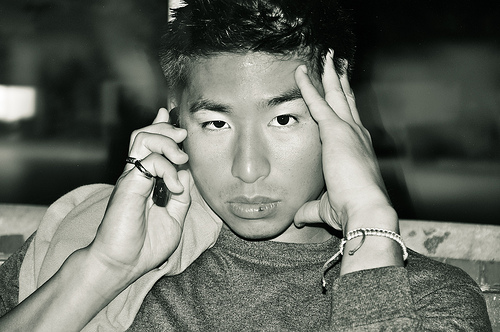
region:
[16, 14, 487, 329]
a boy on a cell phone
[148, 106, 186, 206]
a cell phone in a hand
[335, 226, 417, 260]
a bracelet on a wrist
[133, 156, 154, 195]
a ring on a finger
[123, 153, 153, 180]
a couple of rings on fingers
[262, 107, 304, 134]
th eye of a boy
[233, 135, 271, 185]
the nose of a boy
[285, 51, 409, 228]
a left hand of a boy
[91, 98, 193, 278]
the right hand of a boy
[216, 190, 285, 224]
the lips on a boy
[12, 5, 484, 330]
a man holds a cell phone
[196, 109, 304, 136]
eyes are black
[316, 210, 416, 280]
bracelet on a wrist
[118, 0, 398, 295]
boy has short hair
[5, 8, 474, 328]
man holds a phone on right hand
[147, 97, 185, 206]
cell phone is black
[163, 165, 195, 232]
thumb holding a phone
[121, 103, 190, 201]
four fingers over a black phone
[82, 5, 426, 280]
man has black hair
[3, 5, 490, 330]
man wears a gray top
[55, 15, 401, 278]
man talking on phone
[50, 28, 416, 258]
man holding cell phone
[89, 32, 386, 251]
man listening on phone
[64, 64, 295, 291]
man holding phone in hand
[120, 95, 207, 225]
hand with a black phone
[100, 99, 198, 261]
two rings on hand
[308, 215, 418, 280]
bracelet on man's wrist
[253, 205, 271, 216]
black mark on man's lip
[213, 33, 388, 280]
hand on side of man's face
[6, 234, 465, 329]
man wearing a black sweater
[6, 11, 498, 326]
A man talking on a cell phone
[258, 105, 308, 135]
A man's left eye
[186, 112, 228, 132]
A man's right eye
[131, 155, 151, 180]
A ring on a man's finger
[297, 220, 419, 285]
A bracelet on a man's wrist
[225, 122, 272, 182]
A man's nose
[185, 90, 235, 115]
A man's right eyebrow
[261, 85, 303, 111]
A mans left eyebrow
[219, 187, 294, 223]
A man's mouth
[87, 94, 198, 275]
A man's hand holding a cell phone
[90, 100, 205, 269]
hand holding black phone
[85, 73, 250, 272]
hand holding a phone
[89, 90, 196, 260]
hand holding a cell phone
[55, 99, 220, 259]
cell phone in a hand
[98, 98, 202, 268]
cell phone in man's hand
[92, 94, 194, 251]
hand with two rings on it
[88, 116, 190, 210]
rings on man's fingers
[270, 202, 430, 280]
bracelet on man's arm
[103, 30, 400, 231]
man holding head while talking on phone